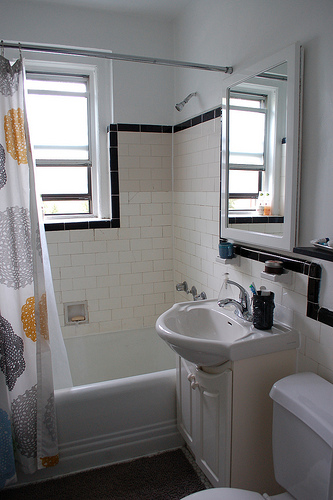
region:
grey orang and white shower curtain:
[0, 59, 71, 469]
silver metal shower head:
[174, 92, 197, 113]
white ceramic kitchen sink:
[156, 300, 286, 366]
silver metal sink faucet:
[218, 280, 251, 319]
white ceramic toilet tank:
[271, 375, 332, 499]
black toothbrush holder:
[253, 291, 273, 330]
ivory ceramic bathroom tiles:
[118, 117, 221, 193]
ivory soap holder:
[63, 302, 92, 325]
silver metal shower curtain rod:
[0, 41, 233, 74]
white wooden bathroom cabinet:
[176, 352, 298, 492]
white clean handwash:
[153, 288, 299, 369]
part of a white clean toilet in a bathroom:
[174, 371, 332, 496]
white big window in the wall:
[0, 72, 102, 216]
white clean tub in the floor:
[0, 316, 203, 476]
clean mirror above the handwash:
[217, 67, 299, 245]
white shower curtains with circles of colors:
[1, 68, 58, 485]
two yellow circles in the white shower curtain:
[0, 103, 58, 345]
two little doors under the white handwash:
[171, 360, 236, 478]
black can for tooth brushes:
[253, 288, 277, 333]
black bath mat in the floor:
[3, 440, 210, 498]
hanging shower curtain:
[4, 73, 54, 490]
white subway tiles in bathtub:
[114, 129, 213, 305]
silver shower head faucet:
[167, 86, 203, 115]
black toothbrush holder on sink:
[248, 281, 276, 329]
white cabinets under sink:
[173, 354, 241, 486]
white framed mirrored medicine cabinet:
[219, 71, 302, 251]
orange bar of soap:
[66, 307, 91, 328]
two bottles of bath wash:
[252, 186, 279, 219]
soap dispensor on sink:
[212, 267, 241, 310]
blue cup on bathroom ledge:
[213, 237, 240, 262]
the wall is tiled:
[100, 110, 219, 296]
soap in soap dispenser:
[59, 305, 110, 342]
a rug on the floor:
[57, 452, 185, 497]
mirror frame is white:
[210, 50, 301, 269]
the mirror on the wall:
[202, 32, 313, 290]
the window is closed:
[21, 54, 121, 233]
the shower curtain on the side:
[7, 40, 133, 464]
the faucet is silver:
[204, 260, 250, 329]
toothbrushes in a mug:
[239, 280, 278, 340]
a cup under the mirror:
[214, 230, 249, 274]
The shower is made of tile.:
[128, 148, 203, 244]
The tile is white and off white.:
[133, 147, 196, 228]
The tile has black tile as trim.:
[121, 112, 167, 143]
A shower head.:
[159, 85, 204, 134]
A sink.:
[150, 290, 301, 361]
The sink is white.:
[148, 287, 294, 366]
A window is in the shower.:
[5, 50, 112, 226]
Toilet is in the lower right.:
[165, 366, 332, 499]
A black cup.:
[239, 276, 278, 333]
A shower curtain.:
[0, 38, 77, 468]